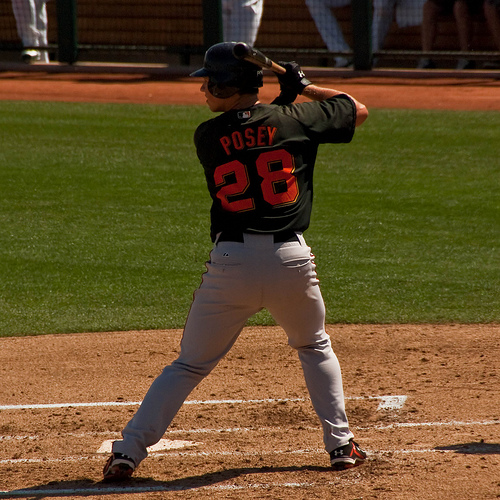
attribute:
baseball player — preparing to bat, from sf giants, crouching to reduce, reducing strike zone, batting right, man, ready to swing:
[96, 38, 370, 484]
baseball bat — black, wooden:
[233, 42, 289, 80]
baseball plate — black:
[99, 434, 200, 455]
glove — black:
[281, 61, 311, 92]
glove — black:
[276, 76, 299, 104]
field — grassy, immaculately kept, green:
[2, 97, 499, 500]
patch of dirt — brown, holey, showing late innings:
[1, 312, 499, 499]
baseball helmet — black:
[190, 41, 262, 79]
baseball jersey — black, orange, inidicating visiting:
[190, 93, 355, 235]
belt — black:
[212, 230, 304, 246]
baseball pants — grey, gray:
[107, 233, 353, 454]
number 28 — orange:
[211, 149, 305, 216]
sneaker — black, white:
[99, 450, 137, 481]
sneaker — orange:
[327, 436, 367, 466]